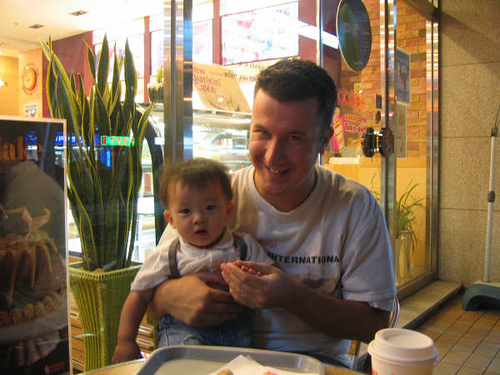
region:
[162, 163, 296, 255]
Little boy has dark hair.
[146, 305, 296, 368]
Little boy wearing jeans.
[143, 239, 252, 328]
Little boy wearing white shirt.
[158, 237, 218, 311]
Little boy is wearing suspenders.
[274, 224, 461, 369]
Man is wearing white shirt.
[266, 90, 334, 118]
Man has dark hair.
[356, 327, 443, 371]
White coffee cup on table.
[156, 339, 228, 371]
Gray tray on table.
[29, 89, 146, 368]
Large green plant in background.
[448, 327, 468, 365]
Brown tiles on the ground.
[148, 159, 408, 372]
the man is wearing a shirt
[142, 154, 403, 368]
the mans shirt is white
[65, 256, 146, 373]
the plant is in a green vase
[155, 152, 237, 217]
the baby has short hair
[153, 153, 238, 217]
the baby has brown hair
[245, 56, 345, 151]
the man has short hair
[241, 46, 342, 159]
the man has brown hair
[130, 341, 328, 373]
the tray is grey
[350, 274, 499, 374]
the floor is tile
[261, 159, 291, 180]
the man is smiling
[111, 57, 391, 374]
Man holding a baby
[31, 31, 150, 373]
Plant behind the man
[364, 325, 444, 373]
White cup on the table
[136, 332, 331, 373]
Gray tray on the table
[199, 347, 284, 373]
Napkin on the tray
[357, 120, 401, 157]
Metal lock on the door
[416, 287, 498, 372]
floor made of bricks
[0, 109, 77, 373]
A picture on the wall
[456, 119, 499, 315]
Scraper pan on the floor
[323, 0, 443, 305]
doors made of glass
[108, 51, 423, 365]
a man with a young boy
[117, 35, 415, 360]
the man is holding the boy in his lap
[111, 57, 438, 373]
the man and boy are at a table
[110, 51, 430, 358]
the man is holding the child's hand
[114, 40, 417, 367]
the man and child are looking at the camera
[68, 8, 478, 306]
a store is behind the people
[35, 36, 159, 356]
a plant in a green vase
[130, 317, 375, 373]
a tray is on the table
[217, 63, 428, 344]
the man wears a white shirt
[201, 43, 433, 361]
the man is smiling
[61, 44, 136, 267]
green potted plant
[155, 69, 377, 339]
man holding a baby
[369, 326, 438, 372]
disposable to-go cup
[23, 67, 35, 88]
clock hanging on the wall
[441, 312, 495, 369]
square outdoor tiles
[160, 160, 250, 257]
baby wearing a white shirt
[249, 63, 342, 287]
man wearing a white shirt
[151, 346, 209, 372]
fast food tray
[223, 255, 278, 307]
man's hand holding a baby's hand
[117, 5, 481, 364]
outside a restaurant at night